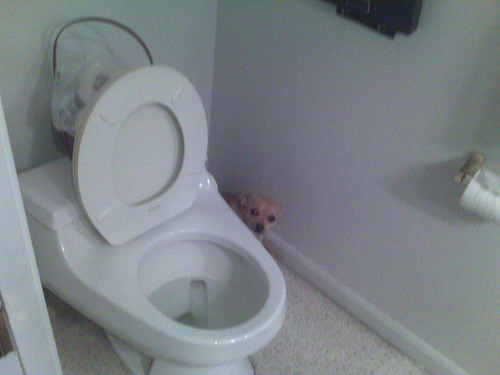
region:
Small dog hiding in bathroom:
[222, 192, 282, 264]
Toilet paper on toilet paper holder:
[452, 150, 499, 223]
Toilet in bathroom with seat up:
[16, 63, 288, 373]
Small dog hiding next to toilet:
[19, 64, 289, 374]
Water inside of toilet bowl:
[147, 275, 267, 332]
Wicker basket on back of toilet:
[51, 14, 153, 161]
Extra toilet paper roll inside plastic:
[49, 27, 138, 136]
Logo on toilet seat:
[146, 203, 163, 213]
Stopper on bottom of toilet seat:
[97, 109, 116, 126]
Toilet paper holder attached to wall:
[451, 150, 483, 186]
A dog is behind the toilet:
[210, 177, 297, 251]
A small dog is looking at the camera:
[220, 178, 292, 252]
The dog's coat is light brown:
[218, 181, 285, 241]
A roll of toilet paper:
[450, 143, 499, 229]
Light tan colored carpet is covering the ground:
[41, 247, 442, 373]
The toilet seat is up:
[63, 60, 304, 357]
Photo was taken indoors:
[6, 5, 498, 368]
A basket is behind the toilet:
[28, 2, 192, 171]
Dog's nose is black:
[248, 216, 273, 239]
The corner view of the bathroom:
[3, 1, 498, 373]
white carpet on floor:
[315, 325, 357, 361]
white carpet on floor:
[300, 285, 322, 317]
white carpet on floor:
[307, 292, 364, 338]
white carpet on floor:
[293, 317, 316, 341]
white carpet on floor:
[269, 337, 294, 369]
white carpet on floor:
[298, 271, 353, 321]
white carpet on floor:
[356, 334, 394, 368]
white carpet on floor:
[363, 344, 392, 365]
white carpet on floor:
[79, 341, 95, 352]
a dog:
[225, 180, 288, 226]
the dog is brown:
[235, 189, 283, 234]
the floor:
[302, 320, 370, 372]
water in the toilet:
[172, 285, 217, 319]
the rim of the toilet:
[223, 324, 245, 340]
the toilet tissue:
[468, 179, 496, 212]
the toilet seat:
[82, 154, 109, 181]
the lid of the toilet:
[120, 140, 172, 183]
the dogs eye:
[248, 207, 262, 218]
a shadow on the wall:
[441, 95, 495, 136]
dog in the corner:
[237, 195, 291, 256]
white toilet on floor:
[97, 137, 281, 356]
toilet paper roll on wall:
[452, 162, 498, 230]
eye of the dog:
[266, 212, 279, 225]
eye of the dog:
[250, 205, 263, 215]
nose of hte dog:
[249, 225, 269, 238]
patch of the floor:
[316, 320, 341, 349]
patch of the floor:
[277, 335, 302, 362]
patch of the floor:
[355, 343, 380, 368]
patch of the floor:
[305, 303, 338, 337]